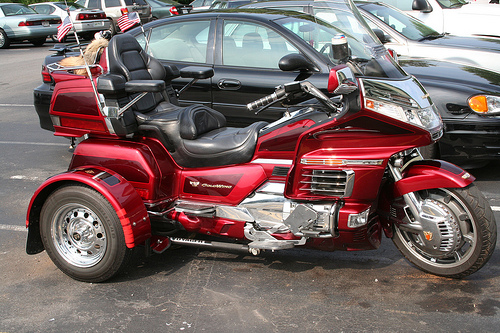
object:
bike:
[23, 0, 498, 284]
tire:
[417, 142, 436, 160]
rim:
[50, 203, 108, 271]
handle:
[244, 90, 285, 113]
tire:
[39, 183, 127, 281]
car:
[32, 5, 500, 174]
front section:
[302, 65, 498, 280]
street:
[0, 43, 499, 332]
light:
[466, 94, 485, 115]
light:
[363, 99, 374, 110]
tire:
[385, 182, 496, 279]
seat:
[104, 33, 269, 170]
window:
[220, 20, 317, 67]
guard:
[311, 0, 444, 137]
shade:
[90, 241, 405, 292]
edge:
[137, 116, 258, 165]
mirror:
[324, 63, 358, 95]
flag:
[54, 17, 76, 43]